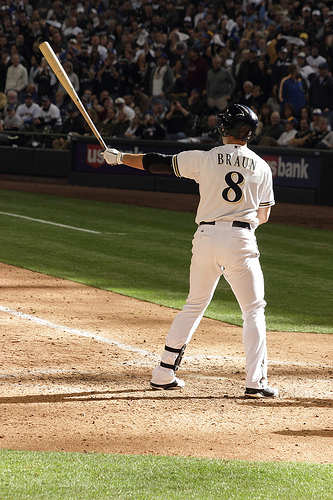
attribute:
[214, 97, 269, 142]
head — black, parted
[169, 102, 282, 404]
man — baseball player, baseball shirt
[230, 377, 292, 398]
shoe — black, white, edged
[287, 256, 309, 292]
grass — green, parted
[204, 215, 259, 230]
belt — leather, black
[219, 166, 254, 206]
number — 8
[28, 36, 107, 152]
baseball bat — brown, wooden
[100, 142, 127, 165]
glove — white, batting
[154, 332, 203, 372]
shin guard — black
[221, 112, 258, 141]
helmet — batting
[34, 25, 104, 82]
bat — baseball, aloft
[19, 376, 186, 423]
shadow — parted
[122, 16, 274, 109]
crowd — people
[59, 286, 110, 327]
dirt — parted, ground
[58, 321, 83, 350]
line — chalk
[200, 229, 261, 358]
white pants — edged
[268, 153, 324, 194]
logo — parted, us bank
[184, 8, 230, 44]
shade — edged, parted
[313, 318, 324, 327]
field — edged